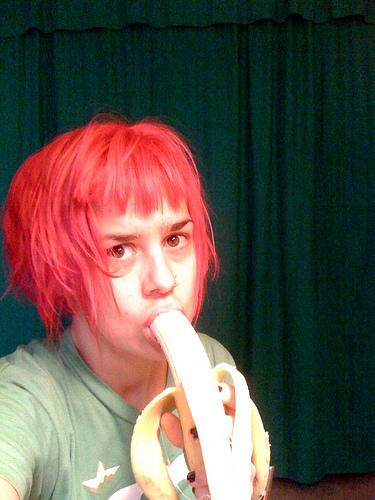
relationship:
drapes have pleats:
[1, 0, 374, 474] [224, 30, 340, 467]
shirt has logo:
[0, 333, 278, 500] [83, 450, 192, 500]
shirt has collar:
[0, 333, 278, 500] [54, 327, 146, 426]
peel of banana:
[116, 386, 183, 498] [143, 307, 248, 500]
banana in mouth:
[143, 307, 248, 500] [138, 304, 192, 344]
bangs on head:
[75, 123, 199, 219] [5, 112, 221, 339]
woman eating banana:
[5, 111, 280, 499] [143, 307, 248, 500]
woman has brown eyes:
[5, 111, 280, 499] [100, 228, 192, 262]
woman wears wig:
[5, 111, 280, 499] [5, 112, 221, 339]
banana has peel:
[143, 307, 248, 500] [116, 386, 183, 498]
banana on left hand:
[143, 307, 248, 500] [0, 380, 275, 500]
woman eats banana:
[5, 111, 280, 499] [143, 307, 248, 500]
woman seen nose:
[5, 111, 280, 499] [138, 232, 182, 301]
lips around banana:
[138, 304, 192, 344] [143, 307, 248, 500]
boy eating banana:
[5, 111, 280, 499] [143, 307, 248, 500]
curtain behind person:
[1, 0, 374, 474] [5, 111, 280, 499]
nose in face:
[138, 232, 182, 301] [60, 176, 213, 370]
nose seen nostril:
[138, 232, 182, 301] [143, 279, 177, 300]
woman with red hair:
[5, 111, 280, 499] [5, 112, 221, 339]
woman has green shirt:
[5, 111, 280, 499] [0, 333, 278, 500]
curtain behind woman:
[1, 0, 374, 474] [5, 111, 280, 499]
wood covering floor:
[275, 475, 373, 500] [264, 419, 371, 493]